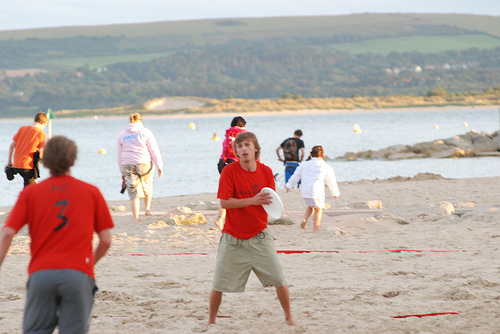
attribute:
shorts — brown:
[112, 156, 172, 206]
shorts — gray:
[15, 256, 110, 326]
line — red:
[116, 237, 461, 256]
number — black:
[50, 197, 68, 232]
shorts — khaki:
[193, 219, 291, 307]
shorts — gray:
[20, 269, 95, 329]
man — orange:
[4, 113, 52, 192]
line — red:
[378, 307, 461, 323]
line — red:
[277, 244, 470, 256]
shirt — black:
[282, 137, 303, 162]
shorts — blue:
[284, 163, 299, 182]